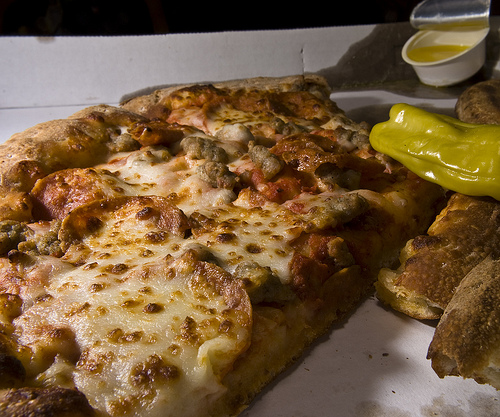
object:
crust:
[0, 75, 441, 414]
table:
[0, 1, 499, 416]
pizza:
[2, 70, 452, 412]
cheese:
[16, 113, 308, 407]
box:
[0, 25, 499, 416]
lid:
[413, 0, 490, 17]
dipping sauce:
[405, 42, 471, 62]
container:
[398, 22, 493, 90]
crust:
[428, 252, 499, 387]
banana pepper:
[368, 104, 499, 203]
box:
[330, 24, 499, 110]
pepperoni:
[56, 193, 191, 254]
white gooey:
[183, 361, 199, 387]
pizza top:
[0, 81, 395, 414]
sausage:
[179, 136, 242, 187]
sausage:
[243, 137, 285, 177]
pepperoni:
[29, 165, 126, 219]